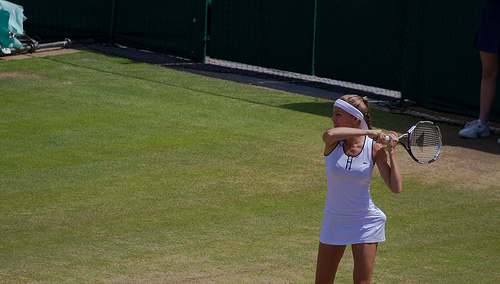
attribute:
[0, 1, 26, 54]
tarp — green 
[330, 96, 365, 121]
sweatband — white 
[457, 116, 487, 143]
shoe — white 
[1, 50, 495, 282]
turf — green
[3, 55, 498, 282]
tenniscourt — grass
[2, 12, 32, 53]
plastic covering — green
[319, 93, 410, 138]
headband — white 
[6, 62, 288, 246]
grass — green 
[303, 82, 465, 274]
female — pretty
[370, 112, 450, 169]
tennis racket — white, black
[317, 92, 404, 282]
woman — young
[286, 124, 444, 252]
dress — tennis, white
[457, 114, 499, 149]
sneaker — white 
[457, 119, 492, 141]
shoe — tennis, white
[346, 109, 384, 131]
hair — blone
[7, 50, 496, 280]
grass — green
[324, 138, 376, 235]
dress — white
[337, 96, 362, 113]
sweatband — white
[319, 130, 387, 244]
dress — white , tennis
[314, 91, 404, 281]
player — tennis, female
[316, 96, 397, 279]
woman — young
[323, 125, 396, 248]
tennis outfit — white